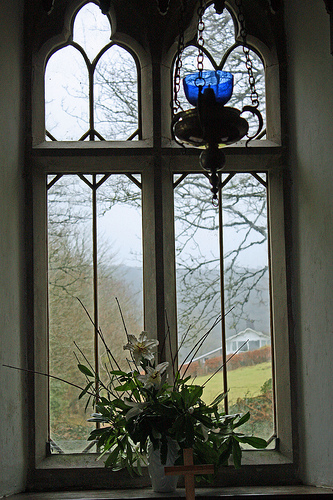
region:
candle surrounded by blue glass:
[175, 65, 239, 112]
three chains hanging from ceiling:
[170, 23, 259, 59]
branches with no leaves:
[230, 213, 264, 296]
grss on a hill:
[236, 364, 265, 393]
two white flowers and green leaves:
[122, 330, 189, 415]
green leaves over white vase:
[140, 413, 186, 496]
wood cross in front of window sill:
[163, 444, 215, 496]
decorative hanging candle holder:
[168, 103, 260, 177]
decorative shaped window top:
[33, 2, 152, 158]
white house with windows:
[232, 325, 265, 354]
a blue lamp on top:
[175, 57, 250, 150]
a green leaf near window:
[86, 352, 265, 488]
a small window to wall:
[43, 168, 272, 491]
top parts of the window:
[51, 17, 284, 144]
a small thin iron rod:
[208, 182, 234, 484]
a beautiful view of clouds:
[62, 230, 289, 352]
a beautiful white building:
[208, 315, 276, 366]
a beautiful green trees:
[56, 206, 118, 430]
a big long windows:
[33, 15, 323, 498]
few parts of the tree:
[158, 330, 235, 404]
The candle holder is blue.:
[187, 70, 233, 97]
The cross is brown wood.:
[164, 445, 212, 492]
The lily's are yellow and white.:
[115, 327, 166, 378]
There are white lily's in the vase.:
[123, 337, 164, 384]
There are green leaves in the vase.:
[148, 402, 226, 432]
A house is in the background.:
[226, 315, 264, 365]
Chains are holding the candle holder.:
[235, 22, 255, 87]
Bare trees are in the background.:
[55, 222, 85, 304]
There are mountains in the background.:
[99, 260, 139, 302]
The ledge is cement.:
[225, 477, 312, 495]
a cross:
[177, 460, 191, 471]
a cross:
[147, 416, 220, 492]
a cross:
[191, 423, 233, 493]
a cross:
[162, 446, 204, 484]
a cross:
[173, 460, 203, 498]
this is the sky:
[102, 215, 131, 236]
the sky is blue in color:
[117, 211, 129, 230]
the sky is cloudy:
[201, 240, 221, 249]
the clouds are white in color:
[202, 242, 219, 262]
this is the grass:
[234, 372, 249, 381]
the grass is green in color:
[231, 371, 242, 379]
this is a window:
[16, 132, 266, 438]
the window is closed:
[55, 122, 251, 338]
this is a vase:
[145, 435, 183, 489]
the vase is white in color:
[148, 456, 163, 481]